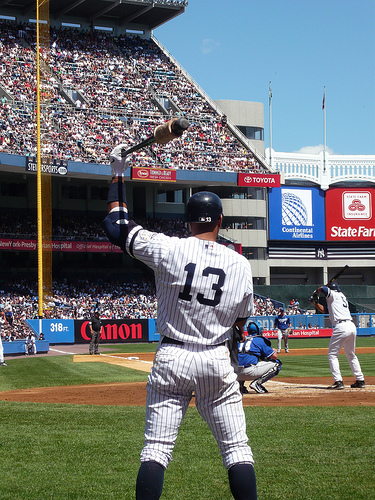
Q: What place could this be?
A: It is a stadium.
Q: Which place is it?
A: It is a stadium.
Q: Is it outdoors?
A: Yes, it is outdoors.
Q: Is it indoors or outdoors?
A: It is outdoors.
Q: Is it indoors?
A: No, it is outdoors.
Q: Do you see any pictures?
A: No, there are no pictures.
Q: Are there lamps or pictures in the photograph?
A: No, there are no pictures or lamps.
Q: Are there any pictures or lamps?
A: No, there are no pictures or lamps.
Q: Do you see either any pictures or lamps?
A: No, there are no pictures or lamps.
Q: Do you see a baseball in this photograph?
A: Yes, there is a baseball.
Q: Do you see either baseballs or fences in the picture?
A: Yes, there is a baseball.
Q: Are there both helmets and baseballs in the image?
A: Yes, there are both a baseball and a helmet.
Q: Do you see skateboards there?
A: No, there are no skateboards.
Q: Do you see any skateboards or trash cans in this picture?
A: No, there are no skateboards or trash cans.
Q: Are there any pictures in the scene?
A: No, there are no pictures.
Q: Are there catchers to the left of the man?
A: Yes, there is a catcher to the left of the man.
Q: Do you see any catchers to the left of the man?
A: Yes, there is a catcher to the left of the man.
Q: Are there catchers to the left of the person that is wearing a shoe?
A: Yes, there is a catcher to the left of the man.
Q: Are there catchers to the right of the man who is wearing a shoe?
A: No, the catcher is to the left of the man.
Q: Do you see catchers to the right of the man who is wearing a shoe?
A: No, the catcher is to the left of the man.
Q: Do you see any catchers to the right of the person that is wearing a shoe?
A: No, the catcher is to the left of the man.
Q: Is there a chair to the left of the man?
A: No, there is a catcher to the left of the man.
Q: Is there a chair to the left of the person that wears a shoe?
A: No, there is a catcher to the left of the man.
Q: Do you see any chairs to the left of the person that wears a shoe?
A: No, there is a catcher to the left of the man.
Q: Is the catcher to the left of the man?
A: Yes, the catcher is to the left of the man.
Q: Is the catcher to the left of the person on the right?
A: Yes, the catcher is to the left of the man.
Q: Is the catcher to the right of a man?
A: No, the catcher is to the left of a man.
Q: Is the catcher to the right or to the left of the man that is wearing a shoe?
A: The catcher is to the left of the man.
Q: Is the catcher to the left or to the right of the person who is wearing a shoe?
A: The catcher is to the left of the man.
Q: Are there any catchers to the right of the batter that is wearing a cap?
A: Yes, there is a catcher to the right of the batter.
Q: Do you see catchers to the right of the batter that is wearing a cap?
A: Yes, there is a catcher to the right of the batter.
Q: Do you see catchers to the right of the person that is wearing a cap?
A: Yes, there is a catcher to the right of the batter.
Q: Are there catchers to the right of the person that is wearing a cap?
A: Yes, there is a catcher to the right of the batter.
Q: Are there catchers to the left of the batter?
A: No, the catcher is to the right of the batter.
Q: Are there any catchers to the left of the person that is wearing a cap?
A: No, the catcher is to the right of the batter.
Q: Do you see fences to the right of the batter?
A: No, there is a catcher to the right of the batter.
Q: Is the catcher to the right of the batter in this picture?
A: Yes, the catcher is to the right of the batter.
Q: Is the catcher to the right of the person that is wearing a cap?
A: Yes, the catcher is to the right of the batter.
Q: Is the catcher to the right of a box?
A: No, the catcher is to the right of the batter.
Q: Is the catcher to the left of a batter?
A: No, the catcher is to the right of a batter.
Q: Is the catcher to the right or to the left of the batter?
A: The catcher is to the right of the batter.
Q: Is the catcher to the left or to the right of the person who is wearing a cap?
A: The catcher is to the right of the batter.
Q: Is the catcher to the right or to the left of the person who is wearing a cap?
A: The catcher is to the right of the batter.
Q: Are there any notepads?
A: No, there are no notepads.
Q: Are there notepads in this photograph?
A: No, there are no notepads.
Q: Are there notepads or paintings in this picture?
A: No, there are no notepads or paintings.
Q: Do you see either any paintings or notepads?
A: No, there are no notepads or paintings.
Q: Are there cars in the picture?
A: No, there are no cars.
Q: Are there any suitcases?
A: No, there are no suitcases.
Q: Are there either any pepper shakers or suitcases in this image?
A: No, there are no suitcases or pepper shakers.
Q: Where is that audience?
A: The audience is in the bleachers.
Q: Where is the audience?
A: The audience is in the bleachers.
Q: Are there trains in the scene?
A: No, there are no trains.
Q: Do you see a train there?
A: No, there are no trains.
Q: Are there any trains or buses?
A: No, there are no trains or buses.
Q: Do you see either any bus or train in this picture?
A: No, there are no trains or buses.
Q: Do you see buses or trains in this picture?
A: No, there are no trains or buses.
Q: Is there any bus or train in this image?
A: No, there are no trains or buses.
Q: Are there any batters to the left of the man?
A: Yes, there is a batter to the left of the man.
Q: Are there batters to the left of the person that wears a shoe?
A: Yes, there is a batter to the left of the man.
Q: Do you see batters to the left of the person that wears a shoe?
A: Yes, there is a batter to the left of the man.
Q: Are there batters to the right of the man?
A: No, the batter is to the left of the man.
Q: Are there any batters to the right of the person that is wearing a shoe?
A: No, the batter is to the left of the man.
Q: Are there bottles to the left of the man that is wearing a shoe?
A: No, there is a batter to the left of the man.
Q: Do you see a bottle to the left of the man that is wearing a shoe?
A: No, there is a batter to the left of the man.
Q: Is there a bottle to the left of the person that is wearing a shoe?
A: No, there is a batter to the left of the man.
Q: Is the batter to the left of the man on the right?
A: Yes, the batter is to the left of the man.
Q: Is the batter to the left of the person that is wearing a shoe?
A: Yes, the batter is to the left of the man.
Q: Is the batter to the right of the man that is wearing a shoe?
A: No, the batter is to the left of the man.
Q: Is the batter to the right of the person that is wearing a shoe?
A: No, the batter is to the left of the man.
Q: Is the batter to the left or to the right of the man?
A: The batter is to the left of the man.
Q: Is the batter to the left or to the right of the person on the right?
A: The batter is to the left of the man.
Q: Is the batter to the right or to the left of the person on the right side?
A: The batter is to the left of the man.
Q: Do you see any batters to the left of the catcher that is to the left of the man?
A: Yes, there is a batter to the left of the catcher.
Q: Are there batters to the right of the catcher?
A: No, the batter is to the left of the catcher.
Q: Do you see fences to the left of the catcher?
A: No, there is a batter to the left of the catcher.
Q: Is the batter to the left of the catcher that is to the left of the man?
A: Yes, the batter is to the left of the catcher.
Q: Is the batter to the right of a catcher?
A: No, the batter is to the left of a catcher.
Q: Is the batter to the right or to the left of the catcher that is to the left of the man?
A: The batter is to the left of the catcher.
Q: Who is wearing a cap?
A: The batter is wearing a cap.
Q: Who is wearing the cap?
A: The batter is wearing a cap.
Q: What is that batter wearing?
A: The batter is wearing a cap.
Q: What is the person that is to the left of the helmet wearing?
A: The batter is wearing a cap.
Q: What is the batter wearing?
A: The batter is wearing a cap.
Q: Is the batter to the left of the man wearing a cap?
A: Yes, the batter is wearing a cap.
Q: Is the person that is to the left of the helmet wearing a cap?
A: Yes, the batter is wearing a cap.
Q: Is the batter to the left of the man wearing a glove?
A: No, the batter is wearing a cap.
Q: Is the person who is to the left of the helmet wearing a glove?
A: No, the batter is wearing a cap.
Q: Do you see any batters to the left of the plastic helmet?
A: Yes, there is a batter to the left of the helmet.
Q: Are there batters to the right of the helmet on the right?
A: No, the batter is to the left of the helmet.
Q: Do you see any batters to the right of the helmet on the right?
A: No, the batter is to the left of the helmet.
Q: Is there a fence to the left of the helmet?
A: No, there is a batter to the left of the helmet.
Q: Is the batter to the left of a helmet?
A: Yes, the batter is to the left of a helmet.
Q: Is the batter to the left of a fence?
A: No, the batter is to the left of a helmet.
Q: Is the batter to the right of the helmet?
A: No, the batter is to the left of the helmet.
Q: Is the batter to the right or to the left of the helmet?
A: The batter is to the left of the helmet.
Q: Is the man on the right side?
A: Yes, the man is on the right of the image.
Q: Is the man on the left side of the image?
A: No, the man is on the right of the image.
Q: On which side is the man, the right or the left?
A: The man is on the right of the image.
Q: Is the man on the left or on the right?
A: The man is on the right of the image.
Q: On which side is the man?
A: The man is on the right of the image.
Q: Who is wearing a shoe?
A: The man is wearing a shoe.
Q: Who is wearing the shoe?
A: The man is wearing a shoe.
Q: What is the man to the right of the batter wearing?
A: The man is wearing a shoe.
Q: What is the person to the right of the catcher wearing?
A: The man is wearing a shoe.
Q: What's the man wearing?
A: The man is wearing a shoe.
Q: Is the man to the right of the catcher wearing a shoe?
A: Yes, the man is wearing a shoe.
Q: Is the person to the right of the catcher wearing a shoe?
A: Yes, the man is wearing a shoe.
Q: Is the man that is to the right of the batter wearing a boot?
A: No, the man is wearing a shoe.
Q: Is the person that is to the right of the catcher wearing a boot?
A: No, the man is wearing a shoe.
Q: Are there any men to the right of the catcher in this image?
A: Yes, there is a man to the right of the catcher.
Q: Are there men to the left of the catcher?
A: No, the man is to the right of the catcher.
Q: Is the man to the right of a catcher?
A: Yes, the man is to the right of a catcher.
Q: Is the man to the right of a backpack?
A: No, the man is to the right of a catcher.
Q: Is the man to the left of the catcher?
A: No, the man is to the right of the catcher.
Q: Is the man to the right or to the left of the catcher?
A: The man is to the right of the catcher.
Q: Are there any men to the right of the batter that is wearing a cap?
A: Yes, there is a man to the right of the batter.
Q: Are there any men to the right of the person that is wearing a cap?
A: Yes, there is a man to the right of the batter.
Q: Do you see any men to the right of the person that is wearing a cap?
A: Yes, there is a man to the right of the batter.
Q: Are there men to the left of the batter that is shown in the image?
A: No, the man is to the right of the batter.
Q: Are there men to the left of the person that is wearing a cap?
A: No, the man is to the right of the batter.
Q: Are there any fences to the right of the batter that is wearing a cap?
A: No, there is a man to the right of the batter.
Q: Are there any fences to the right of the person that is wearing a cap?
A: No, there is a man to the right of the batter.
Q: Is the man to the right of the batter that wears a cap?
A: Yes, the man is to the right of the batter.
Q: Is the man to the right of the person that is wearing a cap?
A: Yes, the man is to the right of the batter.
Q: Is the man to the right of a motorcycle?
A: No, the man is to the right of the batter.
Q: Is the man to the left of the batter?
A: No, the man is to the right of the batter.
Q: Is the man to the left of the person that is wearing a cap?
A: No, the man is to the right of the batter.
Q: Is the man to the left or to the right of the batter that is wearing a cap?
A: The man is to the right of the batter.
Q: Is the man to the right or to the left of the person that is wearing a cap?
A: The man is to the right of the batter.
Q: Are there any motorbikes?
A: No, there are no motorbikes.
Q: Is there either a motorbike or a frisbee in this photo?
A: No, there are no motorcycles or frisbees.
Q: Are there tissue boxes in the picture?
A: No, there are no tissue boxes.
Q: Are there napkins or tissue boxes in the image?
A: No, there are no tissue boxes or napkins.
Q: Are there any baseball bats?
A: Yes, there is a baseball bat.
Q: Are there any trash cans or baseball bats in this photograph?
A: Yes, there is a baseball bat.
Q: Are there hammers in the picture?
A: No, there are no hammers.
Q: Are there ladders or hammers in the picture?
A: No, there are no hammers or ladders.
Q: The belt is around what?
A: The belt is around the trousers.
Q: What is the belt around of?
A: The belt is around the trousers.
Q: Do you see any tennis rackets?
A: No, there are no tennis rackets.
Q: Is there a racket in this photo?
A: No, there are no rackets.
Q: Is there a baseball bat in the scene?
A: Yes, there is a baseball bat.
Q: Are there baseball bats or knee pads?
A: Yes, there is a baseball bat.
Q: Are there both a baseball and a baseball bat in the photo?
A: Yes, there are both a baseball bat and a baseball.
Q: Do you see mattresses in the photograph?
A: No, there are no mattresses.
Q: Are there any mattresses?
A: No, there are no mattresses.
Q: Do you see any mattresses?
A: No, there are no mattresses.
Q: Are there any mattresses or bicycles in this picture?
A: No, there are no mattresses or bicycles.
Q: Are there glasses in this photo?
A: No, there are no glasses.